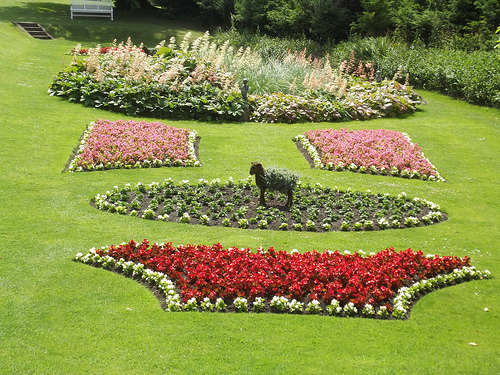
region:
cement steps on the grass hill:
[8, 17, 54, 46]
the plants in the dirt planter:
[62, 236, 498, 353]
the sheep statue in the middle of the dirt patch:
[245, 154, 302, 205]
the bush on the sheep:
[261, 164, 295, 194]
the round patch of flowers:
[89, 178, 463, 236]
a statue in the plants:
[237, 74, 259, 118]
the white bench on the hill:
[64, 0, 121, 30]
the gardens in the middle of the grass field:
[49, 43, 473, 343]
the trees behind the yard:
[228, 3, 498, 53]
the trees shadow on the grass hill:
[3, 3, 68, 52]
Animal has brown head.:
[243, 150, 272, 180]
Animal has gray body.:
[268, 160, 305, 182]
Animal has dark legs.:
[256, 180, 323, 212]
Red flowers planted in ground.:
[374, 275, 392, 297]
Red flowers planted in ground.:
[297, 263, 312, 281]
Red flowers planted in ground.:
[214, 281, 256, 307]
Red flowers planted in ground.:
[131, 244, 149, 262]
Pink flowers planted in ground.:
[171, 133, 183, 152]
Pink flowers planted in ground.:
[398, 143, 409, 153]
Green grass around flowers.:
[9, 70, 447, 360]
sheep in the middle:
[226, 155, 311, 217]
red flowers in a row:
[127, 245, 409, 295]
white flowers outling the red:
[90, 294, 452, 343]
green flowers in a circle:
[119, 186, 419, 230]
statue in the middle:
[232, 64, 262, 131]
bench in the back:
[53, 0, 120, 20]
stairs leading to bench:
[7, 10, 71, 44]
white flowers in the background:
[112, 41, 399, 91]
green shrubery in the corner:
[364, 37, 499, 79]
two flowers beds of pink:
[83, 119, 442, 185]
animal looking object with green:
[236, 148, 303, 203]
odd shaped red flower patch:
[93, 228, 454, 315]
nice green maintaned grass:
[16, 292, 193, 355]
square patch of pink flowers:
[300, 125, 425, 185]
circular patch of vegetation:
[134, 176, 431, 239]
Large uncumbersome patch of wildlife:
[85, 39, 402, 135]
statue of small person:
[237, 70, 267, 114]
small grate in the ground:
[10, 9, 55, 51]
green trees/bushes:
[314, 3, 476, 86]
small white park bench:
[63, 0, 139, 25]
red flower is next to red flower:
[307, 292, 317, 298]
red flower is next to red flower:
[380, 285, 394, 297]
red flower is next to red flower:
[248, 285, 265, 299]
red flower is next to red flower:
[286, 284, 303, 301]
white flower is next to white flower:
[214, 298, 226, 312]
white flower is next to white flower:
[200, 295, 212, 312]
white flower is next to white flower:
[234, 296, 248, 311]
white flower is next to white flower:
[252, 295, 268, 312]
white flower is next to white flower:
[269, 296, 291, 313]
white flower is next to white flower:
[288, 298, 306, 315]